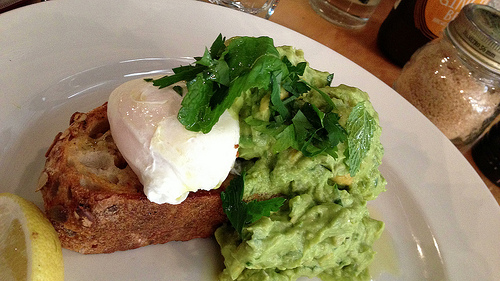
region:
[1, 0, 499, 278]
a white ceramic plate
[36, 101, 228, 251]
a piece of bread on a plate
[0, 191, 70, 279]
a wedge of lemon on a plate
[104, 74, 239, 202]
some sour cream on some bread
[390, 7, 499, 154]
a small glass jar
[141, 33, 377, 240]
some leaves on the food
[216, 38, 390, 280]
some guacamole on a plate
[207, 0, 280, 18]
a drinking glass on a table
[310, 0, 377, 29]
a drinking glass on a table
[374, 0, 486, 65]
A beer bottle on a table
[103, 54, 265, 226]
butter on a piece of meat.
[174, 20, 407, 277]
green sauce near meat.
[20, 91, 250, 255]
a piece of meat on a plate.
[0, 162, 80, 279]
a lemon wedge on a plate.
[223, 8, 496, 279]
A white plate under food.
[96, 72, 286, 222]
a glob of butter on food.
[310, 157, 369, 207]
green slimey food substance.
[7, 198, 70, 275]
a rhine on a lemon.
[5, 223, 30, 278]
a fleshy section of a lemon.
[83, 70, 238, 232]
a large scoop of butter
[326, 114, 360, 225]
this is some guacamole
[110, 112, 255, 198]
this is some sour cream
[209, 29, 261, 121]
these are mint leaves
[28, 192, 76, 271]
this is a lemon wedge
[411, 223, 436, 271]
this is a plate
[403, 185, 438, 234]
the plate is white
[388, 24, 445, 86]
these are some spices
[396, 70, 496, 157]
the spices are in a jar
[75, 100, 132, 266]
this is some bread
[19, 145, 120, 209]
the bread is sliced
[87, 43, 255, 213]
White sour cream on bread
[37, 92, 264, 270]
Brown piece of bread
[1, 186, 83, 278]
Yellow piece of lemon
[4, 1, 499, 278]
White circle plate with food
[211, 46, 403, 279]
Green piece of guacamole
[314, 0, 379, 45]
Small clear glass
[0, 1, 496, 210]
Brown table with food on top of it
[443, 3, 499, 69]
Silver lid on clear jar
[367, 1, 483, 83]
Small brown bottle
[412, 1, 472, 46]
ORange sticker with white lettering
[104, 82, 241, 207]
Sour cream on bread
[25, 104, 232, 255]
Toasted multi grain bread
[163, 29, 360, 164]
Leaves garnished on top of dish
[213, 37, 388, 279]
Green guacamole on bread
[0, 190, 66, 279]
Lemon wedge in front of bread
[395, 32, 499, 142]
Jar of parmesan cheese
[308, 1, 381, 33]
Bottom of clear bottle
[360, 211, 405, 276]
Juice from guacamole on plate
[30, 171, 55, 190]
Oats on top of bread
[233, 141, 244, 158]
Crumb of toast on sour cream